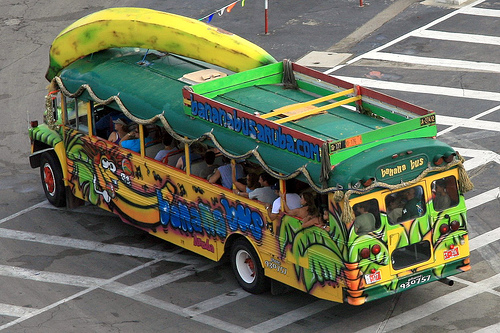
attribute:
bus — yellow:
[30, 5, 472, 309]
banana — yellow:
[46, 8, 280, 83]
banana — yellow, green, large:
[4, 15, 237, 72]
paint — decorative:
[39, 125, 466, 305]